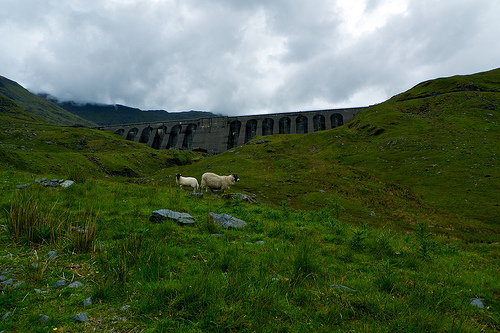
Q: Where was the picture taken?
A: It was taken at the field.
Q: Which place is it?
A: It is a field.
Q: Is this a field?
A: Yes, it is a field.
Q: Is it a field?
A: Yes, it is a field.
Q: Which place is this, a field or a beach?
A: It is a field.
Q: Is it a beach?
A: No, it is a field.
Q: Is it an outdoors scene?
A: Yes, it is outdoors.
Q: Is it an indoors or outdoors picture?
A: It is outdoors.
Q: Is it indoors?
A: No, it is outdoors.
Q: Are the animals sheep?
A: Yes, all the animals are sheep.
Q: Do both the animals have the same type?
A: Yes, all the animals are sheep.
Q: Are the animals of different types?
A: No, all the animals are sheep.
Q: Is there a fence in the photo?
A: No, there are no fences.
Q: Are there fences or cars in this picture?
A: No, there are no fences or cars.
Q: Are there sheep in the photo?
A: Yes, there is a sheep.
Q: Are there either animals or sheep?
A: Yes, there is a sheep.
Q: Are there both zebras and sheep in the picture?
A: No, there is a sheep but no zebras.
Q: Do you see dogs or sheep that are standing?
A: Yes, the sheep is standing.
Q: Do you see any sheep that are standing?
A: Yes, there is a sheep that is standing.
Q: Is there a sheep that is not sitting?
A: Yes, there is a sheep that is standing.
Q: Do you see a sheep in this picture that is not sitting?
A: Yes, there is a sheep that is standing .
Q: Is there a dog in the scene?
A: No, there are no dogs.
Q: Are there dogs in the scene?
A: No, there are no dogs.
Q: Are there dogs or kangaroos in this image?
A: No, there are no dogs or kangaroos.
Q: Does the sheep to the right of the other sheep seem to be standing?
A: Yes, the sheep is standing.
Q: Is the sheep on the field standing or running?
A: The sheep is standing.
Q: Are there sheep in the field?
A: Yes, there is a sheep in the field.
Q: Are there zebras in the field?
A: No, there is a sheep in the field.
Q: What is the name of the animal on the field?
A: The animal is a sheep.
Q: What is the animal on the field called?
A: The animal is a sheep.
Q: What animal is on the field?
A: The animal is a sheep.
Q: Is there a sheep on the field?
A: Yes, there is a sheep on the field.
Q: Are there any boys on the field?
A: No, there is a sheep on the field.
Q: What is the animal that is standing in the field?
A: The animal is a sheep.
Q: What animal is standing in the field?
A: The animal is a sheep.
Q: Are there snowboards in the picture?
A: No, there are no snowboards.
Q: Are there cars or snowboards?
A: No, there are no snowboards or cars.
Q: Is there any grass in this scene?
A: Yes, there is grass.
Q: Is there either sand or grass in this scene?
A: Yes, there is grass.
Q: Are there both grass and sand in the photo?
A: No, there is grass but no sand.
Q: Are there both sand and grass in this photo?
A: No, there is grass but no sand.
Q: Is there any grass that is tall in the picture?
A: Yes, there is tall grass.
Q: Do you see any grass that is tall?
A: Yes, there is grass that is tall.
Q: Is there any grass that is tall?
A: Yes, there is grass that is tall.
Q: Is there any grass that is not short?
A: Yes, there is tall grass.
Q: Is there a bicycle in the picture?
A: No, there are no bicycles.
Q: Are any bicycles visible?
A: No, there are no bicycles.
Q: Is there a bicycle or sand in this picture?
A: No, there are no bicycles or sand.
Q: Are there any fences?
A: No, there are no fences.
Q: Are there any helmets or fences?
A: No, there are no fences or helmets.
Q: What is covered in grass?
A: The hill is covered in grass.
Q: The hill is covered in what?
A: The hill is covered in grass.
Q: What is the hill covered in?
A: The hill is covered in grass.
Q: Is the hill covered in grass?
A: Yes, the hill is covered in grass.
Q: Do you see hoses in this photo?
A: No, there are no hoses.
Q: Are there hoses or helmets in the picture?
A: No, there are no hoses or helmets.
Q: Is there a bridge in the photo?
A: Yes, there is a bridge.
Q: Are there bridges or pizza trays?
A: Yes, there is a bridge.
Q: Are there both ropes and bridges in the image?
A: No, there is a bridge but no ropes.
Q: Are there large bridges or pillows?
A: Yes, there is a large bridge.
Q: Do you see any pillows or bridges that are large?
A: Yes, the bridge is large.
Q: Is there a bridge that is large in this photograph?
A: Yes, there is a large bridge.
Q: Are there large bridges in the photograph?
A: Yes, there is a large bridge.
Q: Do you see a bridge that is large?
A: Yes, there is a bridge that is large.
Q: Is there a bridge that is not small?
A: Yes, there is a large bridge.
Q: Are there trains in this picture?
A: No, there are no trains.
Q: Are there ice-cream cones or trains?
A: No, there are no trains or ice-cream cones.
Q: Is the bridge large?
A: Yes, the bridge is large.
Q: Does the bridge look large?
A: Yes, the bridge is large.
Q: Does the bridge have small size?
A: No, the bridge is large.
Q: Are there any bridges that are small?
A: No, there is a bridge but it is large.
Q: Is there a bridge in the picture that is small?
A: No, there is a bridge but it is large.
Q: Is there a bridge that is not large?
A: No, there is a bridge but it is large.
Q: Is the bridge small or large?
A: The bridge is large.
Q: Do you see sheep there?
A: Yes, there is a sheep.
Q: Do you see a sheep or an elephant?
A: Yes, there is a sheep.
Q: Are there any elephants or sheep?
A: Yes, there is a sheep.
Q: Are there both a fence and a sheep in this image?
A: No, there is a sheep but no fences.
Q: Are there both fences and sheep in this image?
A: No, there is a sheep but no fences.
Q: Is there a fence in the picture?
A: No, there are no fences.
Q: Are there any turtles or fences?
A: No, there are no fences or turtles.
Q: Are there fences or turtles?
A: No, there are no fences or turtles.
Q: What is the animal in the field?
A: The animal is a sheep.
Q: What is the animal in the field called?
A: The animal is a sheep.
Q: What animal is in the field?
A: The animal is a sheep.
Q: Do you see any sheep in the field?
A: Yes, there is a sheep in the field.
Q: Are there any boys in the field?
A: No, there is a sheep in the field.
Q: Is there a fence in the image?
A: No, there are no fences.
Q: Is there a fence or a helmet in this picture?
A: No, there are no fences or helmets.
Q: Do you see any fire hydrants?
A: No, there are no fire hydrants.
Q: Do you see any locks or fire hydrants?
A: No, there are no fire hydrants or locks.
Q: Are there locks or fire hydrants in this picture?
A: No, there are no fire hydrants or locks.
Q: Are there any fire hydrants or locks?
A: No, there are no fire hydrants or locks.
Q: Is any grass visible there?
A: Yes, there is grass.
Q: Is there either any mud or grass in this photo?
A: Yes, there is grass.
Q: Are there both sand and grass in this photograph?
A: No, there is grass but no sand.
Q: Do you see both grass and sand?
A: No, there is grass but no sand.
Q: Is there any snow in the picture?
A: No, there is no snow.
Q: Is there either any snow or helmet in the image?
A: No, there are no snow or helmets.